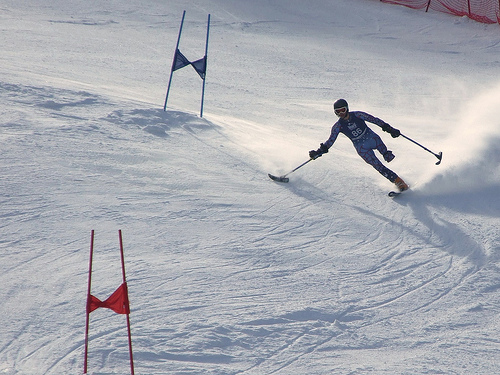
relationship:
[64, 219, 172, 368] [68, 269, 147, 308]
poles with flag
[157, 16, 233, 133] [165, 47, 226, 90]
poles with flag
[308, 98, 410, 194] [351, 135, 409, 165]
person missing leg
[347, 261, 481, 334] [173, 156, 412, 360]
tracks in snow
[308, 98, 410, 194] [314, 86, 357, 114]
person wearing helmet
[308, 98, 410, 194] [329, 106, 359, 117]
person wearing goggles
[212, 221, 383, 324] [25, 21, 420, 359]
snow on hill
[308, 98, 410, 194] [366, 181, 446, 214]
person with ski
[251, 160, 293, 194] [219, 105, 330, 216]
skiis on end of ski poles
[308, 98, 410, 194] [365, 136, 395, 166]
person with half leg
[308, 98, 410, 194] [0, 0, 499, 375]
person skiing hill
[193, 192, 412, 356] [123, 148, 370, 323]
tracks in snow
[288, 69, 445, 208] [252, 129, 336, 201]
person holding ski poles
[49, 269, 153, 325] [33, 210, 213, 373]
flag on poles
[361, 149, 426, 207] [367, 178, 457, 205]
foot on ski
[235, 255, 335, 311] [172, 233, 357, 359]
ground covered snow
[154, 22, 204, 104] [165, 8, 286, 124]
flag on poles